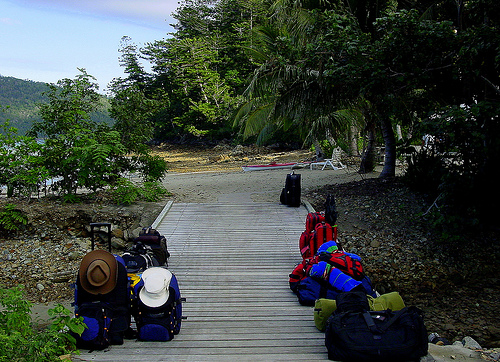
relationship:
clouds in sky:
[95, 2, 179, 26] [2, 1, 216, 95]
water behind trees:
[2, 138, 86, 154] [3, 73, 144, 199]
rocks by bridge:
[426, 335, 498, 361] [88, 204, 346, 361]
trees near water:
[3, 73, 144, 199] [2, 138, 86, 154]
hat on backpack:
[77, 249, 121, 298] [72, 257, 131, 353]